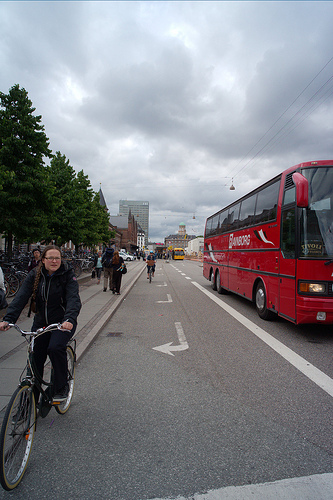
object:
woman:
[0, 241, 81, 404]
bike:
[0, 316, 78, 491]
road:
[138, 282, 202, 459]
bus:
[201, 160, 333, 327]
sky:
[49, 12, 296, 134]